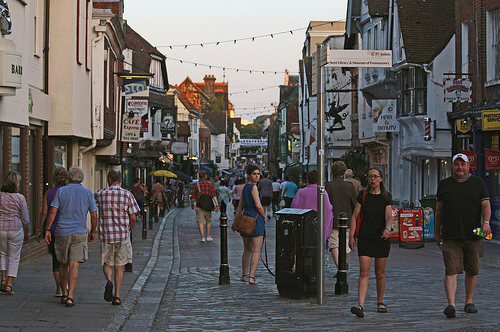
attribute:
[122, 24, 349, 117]
lights — stringed, suspended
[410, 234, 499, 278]
shorts — brown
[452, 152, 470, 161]
cap — white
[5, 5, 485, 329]
scene — outdoors